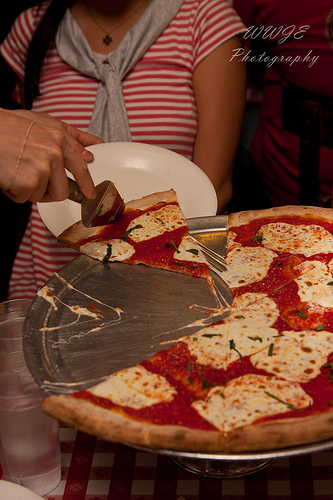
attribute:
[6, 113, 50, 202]
band — rubber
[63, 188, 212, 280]
pizza slice — sliced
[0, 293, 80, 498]
cup — tall , clear , glass 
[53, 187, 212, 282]
pizza — white, red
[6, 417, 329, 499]
table cloth — plaid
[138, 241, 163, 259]
sauce — red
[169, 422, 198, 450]
spot — dark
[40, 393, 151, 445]
crust — brown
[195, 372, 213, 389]
flake — green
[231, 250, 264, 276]
cheese — white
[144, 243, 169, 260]
sauce — red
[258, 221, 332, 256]
cheese — white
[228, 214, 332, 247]
sauce — red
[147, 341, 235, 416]
sauce — red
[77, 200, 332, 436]
sauce — red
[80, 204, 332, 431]
cheese — white